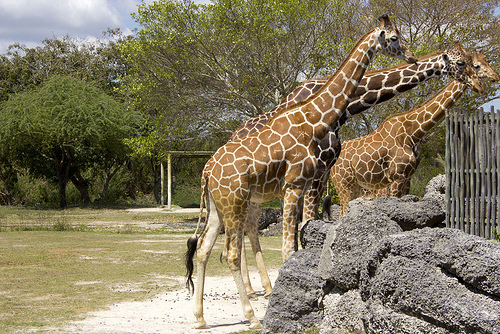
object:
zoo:
[0, 0, 500, 334]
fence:
[445, 112, 497, 238]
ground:
[0, 249, 251, 331]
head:
[370, 15, 419, 66]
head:
[443, 45, 486, 98]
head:
[453, 52, 497, 92]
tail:
[185, 164, 207, 295]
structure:
[159, 149, 201, 206]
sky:
[18, 6, 136, 46]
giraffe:
[182, 12, 411, 332]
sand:
[101, 297, 190, 332]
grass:
[10, 246, 95, 308]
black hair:
[183, 236, 200, 296]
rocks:
[259, 172, 498, 332]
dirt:
[29, 268, 279, 331]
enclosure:
[0, 0, 499, 334]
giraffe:
[223, 41, 498, 297]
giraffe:
[326, 50, 499, 218]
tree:
[0, 65, 143, 207]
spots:
[287, 122, 315, 148]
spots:
[261, 127, 268, 132]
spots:
[288, 110, 305, 126]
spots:
[299, 102, 322, 125]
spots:
[254, 145, 272, 165]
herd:
[179, 11, 498, 328]